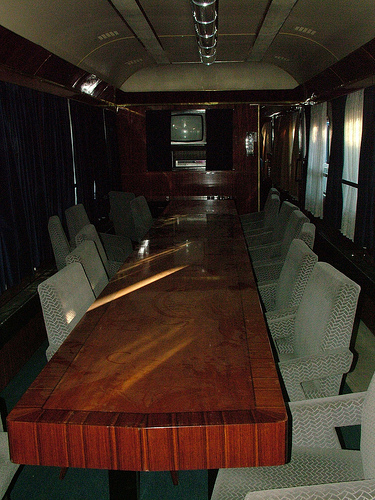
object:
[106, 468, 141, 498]
air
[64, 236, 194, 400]
reflection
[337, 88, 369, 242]
window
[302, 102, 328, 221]
window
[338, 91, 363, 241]
curtain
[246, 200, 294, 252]
chairs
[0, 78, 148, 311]
curtain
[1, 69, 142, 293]
window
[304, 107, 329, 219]
curtains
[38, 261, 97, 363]
chair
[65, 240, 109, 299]
chair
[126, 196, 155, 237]
chair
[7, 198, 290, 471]
desk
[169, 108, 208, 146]
television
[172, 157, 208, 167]
device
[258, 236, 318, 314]
chair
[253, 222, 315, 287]
chair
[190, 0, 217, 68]
lighting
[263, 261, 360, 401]
chair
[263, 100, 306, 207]
curtains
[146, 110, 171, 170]
curtains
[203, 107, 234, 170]
curtains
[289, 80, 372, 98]
cross beam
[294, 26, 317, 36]
vents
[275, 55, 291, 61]
vents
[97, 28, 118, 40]
vents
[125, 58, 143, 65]
vents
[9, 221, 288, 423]
tabletop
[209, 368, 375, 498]
chair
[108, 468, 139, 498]
leg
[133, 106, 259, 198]
stand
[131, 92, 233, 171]
wall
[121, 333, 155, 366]
dust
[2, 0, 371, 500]
train car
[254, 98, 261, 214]
pole